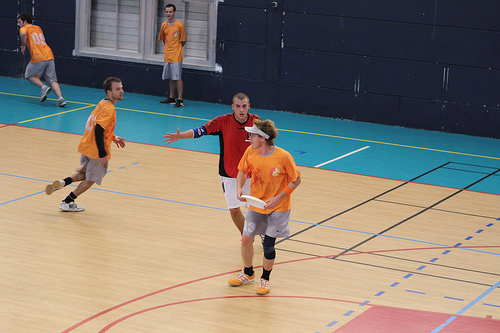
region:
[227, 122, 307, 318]
man wearing a visor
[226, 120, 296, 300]
man wearing orange shirt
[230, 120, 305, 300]
man wearing gray shorts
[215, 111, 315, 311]
man wearing knee brace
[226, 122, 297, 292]
man wearing orange shoes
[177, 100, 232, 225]
man wearing red shirt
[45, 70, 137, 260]
man wearing orange shirt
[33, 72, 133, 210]
man wearing gray shorts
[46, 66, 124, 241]
man wearing black under shirt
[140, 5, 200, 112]
man wearing orange shirt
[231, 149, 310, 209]
t shirt is orange in color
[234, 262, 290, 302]
shoes are orange in color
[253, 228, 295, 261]
leging is black in color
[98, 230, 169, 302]
floor is smooth brown in color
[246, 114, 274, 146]
cape is white in color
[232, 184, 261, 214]
frsibeel is white in color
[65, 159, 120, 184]
short is grey in coor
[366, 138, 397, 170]
floor is light blue in coilor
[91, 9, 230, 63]
window is closed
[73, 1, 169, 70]
window is white in color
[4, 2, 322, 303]
people on basketball court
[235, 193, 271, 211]
white frisbee on court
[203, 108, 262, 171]
red jersey on court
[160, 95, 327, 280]
two people playing frisbee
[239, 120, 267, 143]
white visor on head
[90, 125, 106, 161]
black sleeve on man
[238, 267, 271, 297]
white and yellow shoes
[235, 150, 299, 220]
orange jersey on man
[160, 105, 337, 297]
people playing ultimate frisbee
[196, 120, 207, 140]
blue elbow band on man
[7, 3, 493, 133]
lines with on blue wall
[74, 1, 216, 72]
two windows side by side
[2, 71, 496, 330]
surface of basketball court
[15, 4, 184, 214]
three men in orange shirts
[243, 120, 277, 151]
white visor on head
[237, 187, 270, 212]
frisbee in two hands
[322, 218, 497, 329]
blue broken line on court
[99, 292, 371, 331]
curved red line on court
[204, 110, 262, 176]
red and black shirt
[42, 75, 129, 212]
man running on court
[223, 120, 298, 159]
white visor on head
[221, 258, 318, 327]
yellow and white shoes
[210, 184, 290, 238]
white frisbee in hand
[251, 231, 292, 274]
a black knee brace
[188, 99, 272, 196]
a red and black shirt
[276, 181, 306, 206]
an orange wrist band on arm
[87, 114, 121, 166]
a long black sleeve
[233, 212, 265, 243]
number 13 on shorts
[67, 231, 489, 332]
red lines on ground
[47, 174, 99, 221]
white and black shoes